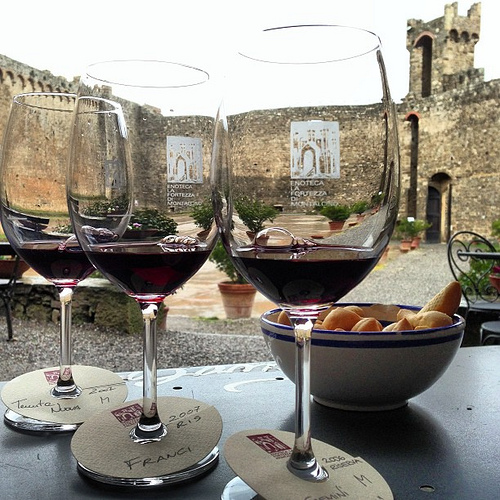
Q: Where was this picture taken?
A: A cafe.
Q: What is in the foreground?
A: Glasses.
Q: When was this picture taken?
A: Daytime.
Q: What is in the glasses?
A: Red wine.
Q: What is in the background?
A: A building.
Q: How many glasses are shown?
A: Three.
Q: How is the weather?
A: Sunny.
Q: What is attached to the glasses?
A: Name Tags.